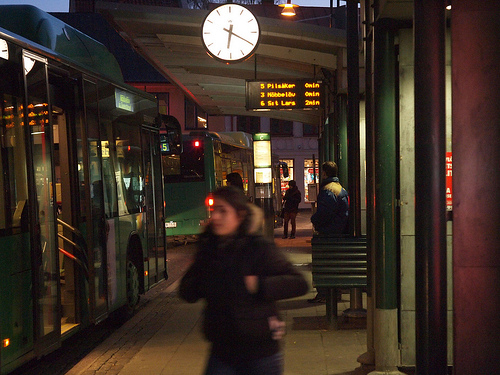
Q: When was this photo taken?
A: In the evening.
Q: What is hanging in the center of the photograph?
A: A clock.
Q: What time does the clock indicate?
A: 6:20.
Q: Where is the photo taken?
A: At a bus station.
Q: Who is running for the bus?
A: A girl in a parka.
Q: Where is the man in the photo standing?
A: Beneath the schedule board.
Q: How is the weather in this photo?
A: Cold.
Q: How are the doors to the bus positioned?
A: Open.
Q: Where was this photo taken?
A: At a bus station.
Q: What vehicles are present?
A: Buses.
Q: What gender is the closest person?
A: Female.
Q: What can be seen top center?
A: Clock.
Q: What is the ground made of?
A: Concrete.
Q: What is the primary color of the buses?
A: Green.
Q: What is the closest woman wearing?
A: A black coat.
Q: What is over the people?
A: Awning.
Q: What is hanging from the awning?
A: A digital board.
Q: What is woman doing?
A: Walking.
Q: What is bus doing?
A: Moving.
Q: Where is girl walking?
A: Sidewalk.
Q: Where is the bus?
A: At curb.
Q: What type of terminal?
A: Bus.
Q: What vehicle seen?
A: Bus.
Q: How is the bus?
A: Parked.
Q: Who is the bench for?
A: Passengers.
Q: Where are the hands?
A: In pocket.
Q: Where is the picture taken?
A: Bus station.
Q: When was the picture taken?
A: 6:20.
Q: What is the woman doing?
A: Walking.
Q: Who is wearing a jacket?
A: The woman.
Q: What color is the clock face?
A: White.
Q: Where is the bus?
A: To the left.